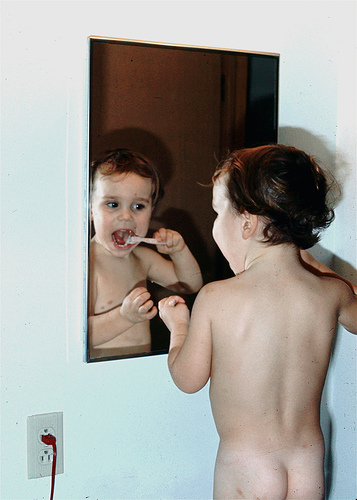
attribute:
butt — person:
[212, 443, 329, 498]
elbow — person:
[168, 370, 214, 408]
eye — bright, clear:
[107, 201, 115, 206]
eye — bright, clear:
[134, 203, 144, 210]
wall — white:
[9, 64, 55, 143]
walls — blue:
[11, 5, 356, 498]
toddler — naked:
[152, 137, 356, 497]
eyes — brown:
[102, 198, 146, 213]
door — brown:
[90, 42, 253, 277]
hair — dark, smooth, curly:
[198, 146, 333, 247]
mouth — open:
[110, 226, 135, 248]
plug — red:
[36, 430, 62, 500]